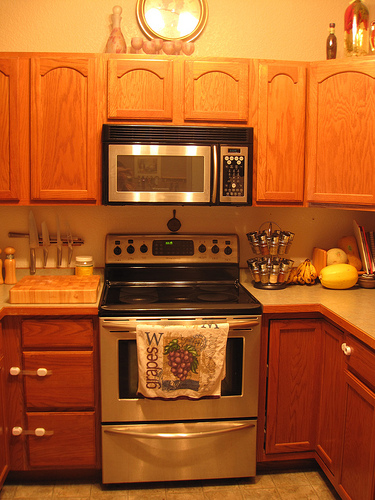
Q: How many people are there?
A: None.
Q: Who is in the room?
A: No one.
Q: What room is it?
A: Kitchen.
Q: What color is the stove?
A: Black and silver.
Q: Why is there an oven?
A: To cook stuff.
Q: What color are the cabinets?
A: Brown.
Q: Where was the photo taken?
A: The kitchen.